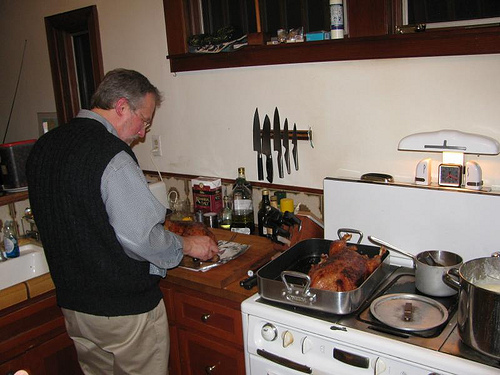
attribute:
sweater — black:
[25, 115, 163, 316]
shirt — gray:
[74, 109, 181, 277]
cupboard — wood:
[159, 281, 248, 373]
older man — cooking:
[22, 55, 230, 372]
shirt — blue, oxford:
[68, 106, 190, 283]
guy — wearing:
[43, 68, 165, 370]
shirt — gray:
[102, 157, 164, 247]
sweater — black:
[35, 140, 126, 310]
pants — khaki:
[60, 306, 167, 373]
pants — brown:
[55, 300, 173, 373]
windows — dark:
[170, 11, 363, 56]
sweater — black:
[23, 108, 171, 320]